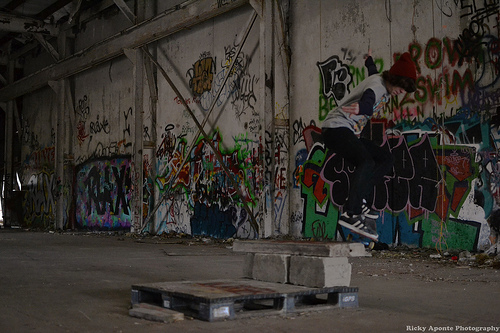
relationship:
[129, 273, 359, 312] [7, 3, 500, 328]
pallet in warehouse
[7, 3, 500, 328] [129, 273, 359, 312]
warehouse has pallet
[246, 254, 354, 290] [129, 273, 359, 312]
cinder block on pallet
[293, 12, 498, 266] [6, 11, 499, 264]
graffiti on wall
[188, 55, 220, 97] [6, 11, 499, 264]
graffiti on wall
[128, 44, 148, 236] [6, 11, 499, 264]
beam on wall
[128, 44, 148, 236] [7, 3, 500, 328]
beam in warehouse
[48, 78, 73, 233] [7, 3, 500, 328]
beam in warehouse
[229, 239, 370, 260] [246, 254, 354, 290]
slab on cinder block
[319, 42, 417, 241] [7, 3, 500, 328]
skateboarder in warehouse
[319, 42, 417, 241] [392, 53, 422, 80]
skateboarder wearing cap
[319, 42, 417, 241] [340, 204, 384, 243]
skateboarder wearing shoes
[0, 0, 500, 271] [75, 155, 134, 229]
wall has graffiti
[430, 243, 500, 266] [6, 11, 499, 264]
trash near wall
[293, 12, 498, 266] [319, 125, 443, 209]
graffiti has letters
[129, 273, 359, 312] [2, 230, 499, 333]
pallet on ground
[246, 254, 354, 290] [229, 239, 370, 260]
cinder block has board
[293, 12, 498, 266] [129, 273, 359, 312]
graffiti behind pallet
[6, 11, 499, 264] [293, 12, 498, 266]
wall has graffiti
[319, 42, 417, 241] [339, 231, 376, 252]
skateboarder riding skateboard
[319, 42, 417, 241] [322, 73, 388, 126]
skateboarder wearing shirt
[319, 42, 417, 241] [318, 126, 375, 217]
skateboarder wearing clothes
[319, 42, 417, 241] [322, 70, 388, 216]
skateboarder wearing clothes